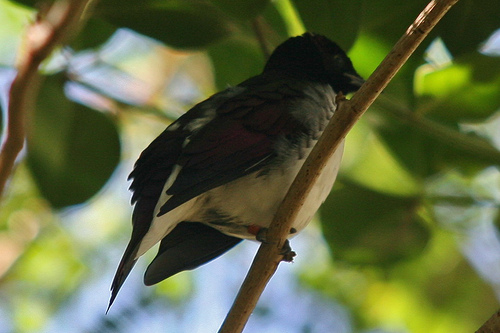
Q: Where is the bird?
A: Branch.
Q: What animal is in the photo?
A: Bird.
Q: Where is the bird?
A: On the branch.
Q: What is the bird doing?
A: Perching.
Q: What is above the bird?
A: Leaves.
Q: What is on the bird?
A: Feathers.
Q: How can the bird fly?
A: With the wings.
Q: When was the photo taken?
A: During the daytime.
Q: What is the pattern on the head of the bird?
A: Solid black.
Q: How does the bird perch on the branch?
A: Claws.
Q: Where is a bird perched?
A: Thin branch.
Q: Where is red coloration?
A: Near the bird's claws.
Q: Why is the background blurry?
A: Out of focus.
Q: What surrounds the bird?
A: Green leaves.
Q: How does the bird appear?
A: Alert and perched.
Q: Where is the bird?
A: In a tree.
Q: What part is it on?
A: A branch.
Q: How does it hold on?
A: Its feet grip the branch.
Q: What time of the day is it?
A: Afternoon.